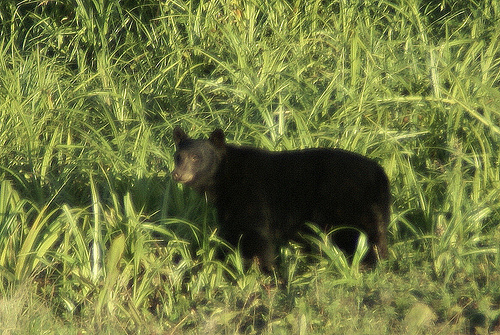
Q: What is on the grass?
A: A bear.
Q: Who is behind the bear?
A: No one.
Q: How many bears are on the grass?
A: One.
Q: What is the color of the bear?
A: Black.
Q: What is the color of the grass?
A: Green.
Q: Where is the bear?
A: On the grass.